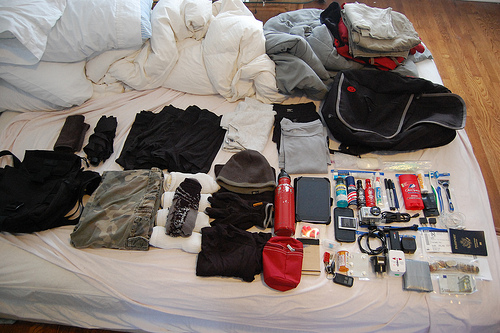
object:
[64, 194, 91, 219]
pattern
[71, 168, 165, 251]
army pants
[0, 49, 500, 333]
mattress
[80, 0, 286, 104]
white sheet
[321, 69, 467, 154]
backpack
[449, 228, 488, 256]
passport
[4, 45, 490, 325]
mattress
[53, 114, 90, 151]
black sock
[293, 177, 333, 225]
ipad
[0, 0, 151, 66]
pillows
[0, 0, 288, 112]
bedding wad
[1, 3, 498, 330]
bed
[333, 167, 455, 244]
items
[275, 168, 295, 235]
bottle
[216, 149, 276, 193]
cap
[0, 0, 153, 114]
pillows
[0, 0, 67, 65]
pillow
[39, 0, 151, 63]
pillow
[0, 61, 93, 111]
pillow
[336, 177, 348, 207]
bottle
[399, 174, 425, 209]
deodorant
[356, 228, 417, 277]
adapter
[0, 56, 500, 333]
white sheet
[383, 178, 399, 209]
ink pens